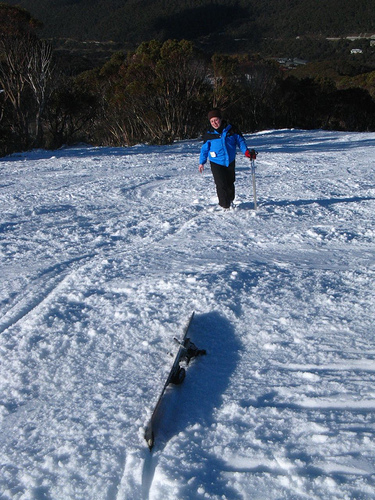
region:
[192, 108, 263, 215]
A person walks in the snow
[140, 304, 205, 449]
A single ski in the snow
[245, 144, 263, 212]
Person holds two ski poles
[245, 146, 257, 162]
Person wears red gloves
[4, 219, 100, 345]
Ski tracks in the snow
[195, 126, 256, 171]
Person wears a blue and black jacket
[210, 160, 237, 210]
Person wears black pants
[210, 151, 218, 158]
A white piece of paper in the jacket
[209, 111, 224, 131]
A hat on the person's head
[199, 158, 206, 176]
A hand without a glove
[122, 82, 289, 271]
person in the snow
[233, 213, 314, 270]
snow under the person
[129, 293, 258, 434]
item in the snow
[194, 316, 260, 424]
shadow on the ground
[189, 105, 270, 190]
blue and black outfit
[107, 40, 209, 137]
trees behind the person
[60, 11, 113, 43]
many trees in the distance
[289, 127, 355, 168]
shadow on the snow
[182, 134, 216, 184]
arm of the person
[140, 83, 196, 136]
branches on the tree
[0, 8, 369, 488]
Photo taken during the day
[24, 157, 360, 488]
Snow covering the ground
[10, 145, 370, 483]
The ground is white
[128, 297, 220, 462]
A ski on the ground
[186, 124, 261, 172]
Blue coat on the person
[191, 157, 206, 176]
No glove on the right hand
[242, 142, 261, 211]
Ski poles in the person's hand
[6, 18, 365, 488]
Photo taken in winter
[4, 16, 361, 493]
The weather is cold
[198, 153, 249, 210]
Black pants on the person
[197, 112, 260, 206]
a person on snowy slope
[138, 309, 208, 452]
a black snowboard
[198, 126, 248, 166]
a black and blue winter coat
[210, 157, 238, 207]
a black pair of snow pants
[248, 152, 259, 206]
a pair of snow poles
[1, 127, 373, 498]
a snowy ski slope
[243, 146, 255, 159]
a red snow glove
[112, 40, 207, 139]
a large tree in distance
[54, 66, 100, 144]
a large tree in distance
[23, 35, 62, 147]
a large tree in distance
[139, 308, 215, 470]
snow board laying in snow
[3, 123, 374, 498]
expanse of snow on ground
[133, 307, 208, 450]
snow board laying on its side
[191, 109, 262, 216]
front of person in blue coat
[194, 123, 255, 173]
black and blue winter coat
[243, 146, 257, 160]
red winter glove on left hand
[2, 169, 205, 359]
long narrow tracks in snow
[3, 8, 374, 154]
grove of trees in distance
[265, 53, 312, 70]
distant roof tops among the trees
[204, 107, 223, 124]
black knitted winter beanie